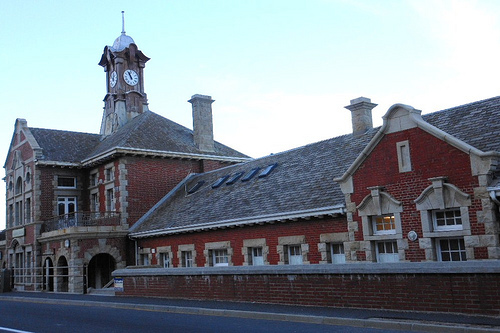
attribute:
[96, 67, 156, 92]
clock — small, tower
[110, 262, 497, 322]
wall — brick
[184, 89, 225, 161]
chimney — grey, smokeless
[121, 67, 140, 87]
clock — white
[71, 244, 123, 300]
entrance — dark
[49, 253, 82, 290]
entrance — dark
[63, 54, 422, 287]
building — large, brick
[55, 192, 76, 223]
door — white, closed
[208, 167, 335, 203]
grey roof — damaged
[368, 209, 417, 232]
light — on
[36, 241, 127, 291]
archways — open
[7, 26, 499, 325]
building — unique